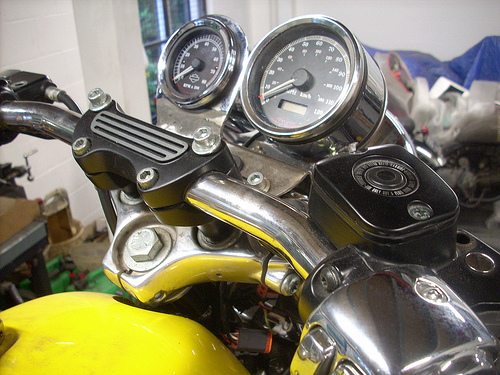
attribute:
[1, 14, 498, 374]
motorcycle — yellow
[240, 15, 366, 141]
speedometer — silver, shiny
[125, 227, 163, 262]
bolt — large, metal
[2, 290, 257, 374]
petrol tank — bright yellow, yellow, painted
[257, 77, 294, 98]
needle — white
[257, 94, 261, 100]
tip — red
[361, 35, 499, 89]
tarp — blue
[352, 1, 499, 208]
area — cluttered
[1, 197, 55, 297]
work bench — metal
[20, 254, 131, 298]
supplies — green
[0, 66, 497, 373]
handles — shiny, silver, chrome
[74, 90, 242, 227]
clamp — black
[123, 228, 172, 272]
washer — large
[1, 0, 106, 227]
wall — cement blocks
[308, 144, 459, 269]
box — black, square